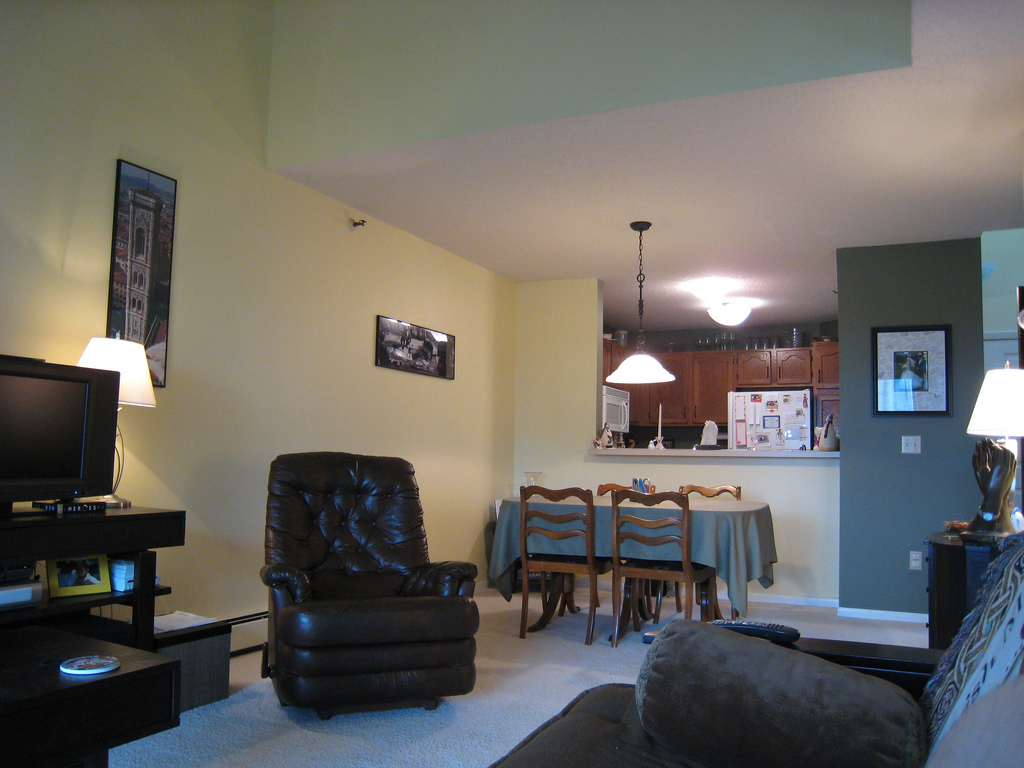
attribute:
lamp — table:
[65, 318, 165, 497]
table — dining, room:
[480, 483, 784, 638]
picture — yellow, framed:
[32, 542, 121, 603]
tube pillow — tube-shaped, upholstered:
[635, 618, 921, 765]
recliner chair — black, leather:
[257, 446, 477, 710]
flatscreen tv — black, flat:
[9, 357, 120, 506]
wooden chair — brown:
[518, 487, 598, 643]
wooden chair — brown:
[598, 485, 694, 642]